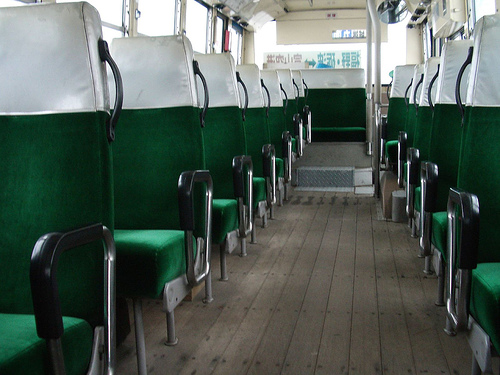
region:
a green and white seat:
[0, 0, 112, 372]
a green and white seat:
[111, 30, 213, 310]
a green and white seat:
[191, 48, 254, 239]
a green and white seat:
[234, 61, 276, 203]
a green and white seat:
[264, 70, 290, 175]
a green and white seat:
[278, 66, 302, 155]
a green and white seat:
[291, 68, 313, 143]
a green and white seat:
[448, 15, 499, 360]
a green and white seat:
[424, 38, 474, 282]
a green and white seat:
[405, 55, 443, 241]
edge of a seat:
[168, 248, 177, 257]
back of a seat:
[336, 116, 352, 158]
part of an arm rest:
[426, 162, 431, 177]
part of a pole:
[208, 286, 218, 306]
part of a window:
[341, 51, 353, 53]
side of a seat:
[255, 183, 278, 215]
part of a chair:
[466, 213, 476, 226]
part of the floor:
[311, 249, 333, 284]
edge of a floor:
[271, 268, 307, 313]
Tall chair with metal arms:
[125, 74, 225, 361]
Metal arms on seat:
[162, 170, 237, 340]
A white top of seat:
[112, 38, 199, 111]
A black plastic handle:
[92, 33, 134, 154]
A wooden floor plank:
[271, 243, 405, 374]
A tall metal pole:
[355, 7, 391, 197]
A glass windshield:
[286, 38, 371, 72]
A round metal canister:
[384, 188, 409, 225]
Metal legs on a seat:
[162, 275, 209, 339]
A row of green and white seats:
[374, 47, 496, 238]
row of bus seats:
[5, 4, 303, 372]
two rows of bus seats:
[4, 4, 494, 371]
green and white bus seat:
[3, 0, 115, 374]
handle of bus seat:
[0, 1, 125, 218]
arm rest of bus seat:
[29, 217, 116, 373]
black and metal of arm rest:
[31, 221, 118, 339]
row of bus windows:
[104, 0, 247, 58]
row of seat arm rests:
[376, 114, 476, 330]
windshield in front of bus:
[254, 12, 411, 69]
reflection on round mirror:
[374, 3, 411, 24]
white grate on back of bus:
[293, 163, 363, 197]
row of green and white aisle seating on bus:
[3, 2, 316, 369]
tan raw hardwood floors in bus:
[138, 183, 458, 373]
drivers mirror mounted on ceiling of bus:
[373, 2, 414, 27]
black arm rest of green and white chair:
[26, 215, 117, 373]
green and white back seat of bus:
[256, 20, 369, 152]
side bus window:
[136, 0, 183, 41]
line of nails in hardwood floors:
[228, 298, 419, 320]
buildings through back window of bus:
[256, 47, 366, 67]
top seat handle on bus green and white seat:
[91, 33, 130, 138]